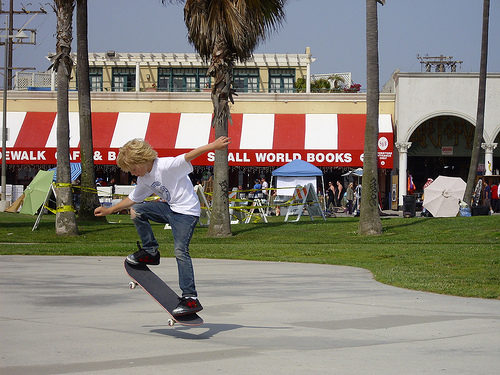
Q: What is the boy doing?
A: Skateboarding.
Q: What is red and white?
A: Awning to bookstore.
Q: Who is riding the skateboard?
A: The boy.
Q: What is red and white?
A: The sign.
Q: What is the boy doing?
A: Skateboarding.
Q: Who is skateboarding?
A: The boy.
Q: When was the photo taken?
A: Afternoon.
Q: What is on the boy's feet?
A: Sneakers.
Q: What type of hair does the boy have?
A: Blonde.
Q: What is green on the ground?
A: Grass.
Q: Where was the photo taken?
A: Near a bookstore.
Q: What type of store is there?
A: Books.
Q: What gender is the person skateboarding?
A: Male.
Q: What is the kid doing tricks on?
A: Skateboard.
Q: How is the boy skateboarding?
A: With feet.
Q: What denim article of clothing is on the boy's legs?
A: Is Jeans.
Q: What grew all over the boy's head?
A: Hair.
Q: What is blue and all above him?
A: The sky.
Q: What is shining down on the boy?
A: Sun.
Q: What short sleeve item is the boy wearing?
A: Shirt.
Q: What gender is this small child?
A: Male.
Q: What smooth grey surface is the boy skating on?
A: Concrete.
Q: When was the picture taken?
A: Daytime.